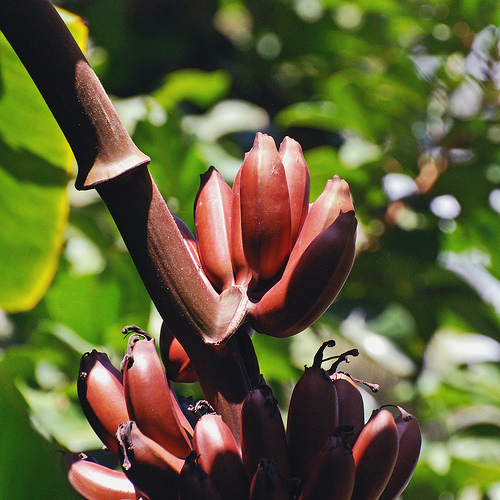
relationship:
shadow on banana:
[133, 379, 425, 491] [60, 332, 425, 491]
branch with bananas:
[7, 4, 258, 374] [173, 119, 359, 340]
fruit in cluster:
[169, 129, 357, 336] [50, 126, 423, 498]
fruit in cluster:
[57, 322, 427, 499] [50, 126, 423, 498]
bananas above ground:
[61, 130, 420, 498] [419, 130, 456, 145]